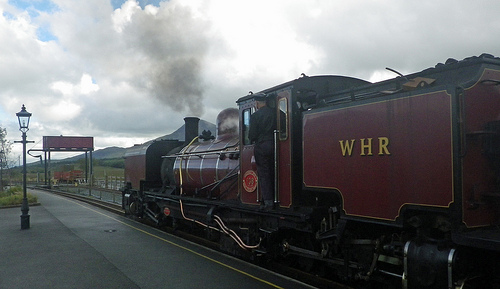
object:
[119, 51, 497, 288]
train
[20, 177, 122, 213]
tracks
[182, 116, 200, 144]
stack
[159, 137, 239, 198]
engine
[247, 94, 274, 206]
engineer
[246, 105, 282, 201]
black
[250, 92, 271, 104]
cap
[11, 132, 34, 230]
lamppost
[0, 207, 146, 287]
pavement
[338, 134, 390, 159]
initials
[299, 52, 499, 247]
car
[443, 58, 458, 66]
coal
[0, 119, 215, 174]
mountains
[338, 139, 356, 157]
letters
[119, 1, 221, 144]
exaust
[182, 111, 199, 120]
out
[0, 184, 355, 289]
platform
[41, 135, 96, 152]
sign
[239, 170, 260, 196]
emblem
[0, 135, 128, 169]
distance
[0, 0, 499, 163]
clouds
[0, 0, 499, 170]
sky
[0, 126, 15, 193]
tree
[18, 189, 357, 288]
sidewalk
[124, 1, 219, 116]
smoke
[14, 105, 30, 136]
light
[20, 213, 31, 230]
base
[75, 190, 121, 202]
railings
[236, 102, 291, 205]
door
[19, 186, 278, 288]
line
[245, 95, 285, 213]
conductor